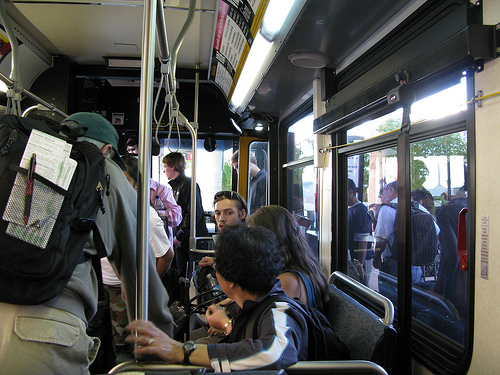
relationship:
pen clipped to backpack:
[22, 152, 35, 225] [0, 112, 106, 306]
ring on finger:
[145, 334, 156, 347] [126, 335, 156, 346]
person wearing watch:
[127, 222, 310, 374] [182, 341, 195, 363]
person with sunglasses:
[214, 190, 246, 230] [212, 192, 244, 202]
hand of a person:
[124, 318, 177, 361] [127, 222, 310, 374]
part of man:
[1, 302, 94, 374] [6, 113, 141, 374]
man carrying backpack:
[6, 113, 141, 374] [0, 112, 106, 306]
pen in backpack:
[22, 152, 35, 225] [0, 112, 106, 306]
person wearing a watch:
[127, 222, 310, 374] [182, 341, 195, 363]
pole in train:
[134, 0, 157, 319] [2, 0, 498, 374]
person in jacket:
[127, 222, 310, 374] [206, 281, 307, 374]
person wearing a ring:
[127, 222, 310, 374] [145, 334, 156, 347]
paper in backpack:
[2, 129, 78, 250] [0, 112, 106, 306]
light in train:
[231, 30, 274, 108] [2, 0, 498, 374]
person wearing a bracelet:
[196, 297, 240, 340] [219, 318, 232, 335]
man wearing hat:
[6, 113, 141, 374] [60, 111, 128, 159]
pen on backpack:
[22, 152, 35, 225] [0, 112, 106, 306]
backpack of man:
[0, 112, 106, 306] [6, 113, 141, 374]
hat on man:
[60, 111, 128, 159] [6, 113, 141, 374]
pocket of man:
[14, 315, 79, 374] [6, 113, 141, 374]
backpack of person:
[307, 304, 348, 360] [127, 222, 310, 374]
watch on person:
[182, 341, 195, 363] [127, 222, 310, 374]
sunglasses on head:
[212, 192, 244, 202] [215, 193, 248, 231]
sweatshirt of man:
[147, 244, 177, 337] [6, 113, 141, 374]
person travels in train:
[127, 222, 310, 374] [2, 0, 498, 374]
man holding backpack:
[6, 113, 141, 374] [0, 112, 106, 306]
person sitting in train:
[127, 222, 310, 374] [2, 0, 498, 374]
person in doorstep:
[231, 148, 268, 217] [234, 130, 277, 219]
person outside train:
[410, 160, 434, 211] [2, 0, 498, 374]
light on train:
[231, 30, 274, 108] [2, 0, 498, 374]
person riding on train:
[196, 297, 240, 340] [2, 0, 498, 374]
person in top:
[194, 205, 330, 346] [272, 267, 320, 324]